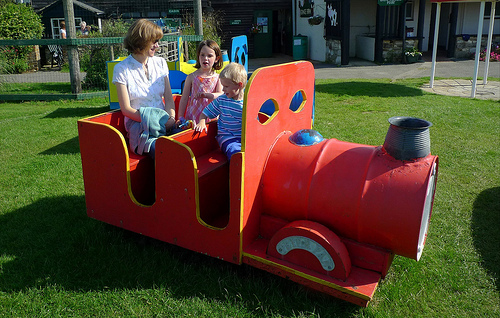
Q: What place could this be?
A: It is a park.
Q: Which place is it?
A: It is a park.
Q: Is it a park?
A: Yes, it is a park.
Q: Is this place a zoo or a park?
A: It is a park.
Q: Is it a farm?
A: No, it is a park.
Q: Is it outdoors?
A: Yes, it is outdoors.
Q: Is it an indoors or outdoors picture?
A: It is outdoors.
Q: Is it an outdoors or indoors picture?
A: It is outdoors.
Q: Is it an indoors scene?
A: No, it is outdoors.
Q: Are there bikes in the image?
A: No, there are no bikes.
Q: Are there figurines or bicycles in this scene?
A: No, there are no bicycles or figurines.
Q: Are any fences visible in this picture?
A: Yes, there is a fence.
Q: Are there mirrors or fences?
A: Yes, there is a fence.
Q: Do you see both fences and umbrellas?
A: No, there is a fence but no umbrellas.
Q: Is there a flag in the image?
A: No, there are no flags.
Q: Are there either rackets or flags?
A: No, there are no flags or rackets.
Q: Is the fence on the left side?
A: Yes, the fence is on the left of the image.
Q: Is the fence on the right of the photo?
A: No, the fence is on the left of the image.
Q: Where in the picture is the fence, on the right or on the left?
A: The fence is on the left of the image.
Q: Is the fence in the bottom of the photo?
A: No, the fence is in the top of the image.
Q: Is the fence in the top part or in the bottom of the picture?
A: The fence is in the top of the image.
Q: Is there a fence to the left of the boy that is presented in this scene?
A: Yes, there is a fence to the left of the boy.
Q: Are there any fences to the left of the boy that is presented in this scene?
A: Yes, there is a fence to the left of the boy.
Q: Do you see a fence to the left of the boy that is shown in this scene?
A: Yes, there is a fence to the left of the boy.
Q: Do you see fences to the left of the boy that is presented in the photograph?
A: Yes, there is a fence to the left of the boy.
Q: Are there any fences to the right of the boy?
A: No, the fence is to the left of the boy.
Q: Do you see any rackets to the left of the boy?
A: No, there is a fence to the left of the boy.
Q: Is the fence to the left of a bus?
A: No, the fence is to the left of a boy.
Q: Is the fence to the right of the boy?
A: No, the fence is to the left of the boy.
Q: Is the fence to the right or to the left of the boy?
A: The fence is to the left of the boy.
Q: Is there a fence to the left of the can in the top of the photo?
A: Yes, there is a fence to the left of the can.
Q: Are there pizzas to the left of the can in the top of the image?
A: No, there is a fence to the left of the can.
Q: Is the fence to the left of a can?
A: Yes, the fence is to the left of a can.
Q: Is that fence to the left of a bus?
A: No, the fence is to the left of a can.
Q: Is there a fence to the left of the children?
A: Yes, there is a fence to the left of the children.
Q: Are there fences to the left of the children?
A: Yes, there is a fence to the left of the children.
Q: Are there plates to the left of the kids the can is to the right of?
A: No, there is a fence to the left of the kids.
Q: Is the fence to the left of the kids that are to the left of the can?
A: Yes, the fence is to the left of the kids.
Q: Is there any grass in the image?
A: Yes, there is grass.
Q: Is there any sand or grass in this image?
A: Yes, there is grass.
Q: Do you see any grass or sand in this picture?
A: Yes, there is grass.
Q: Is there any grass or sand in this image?
A: Yes, there is grass.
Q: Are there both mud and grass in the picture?
A: No, there is grass but no mud.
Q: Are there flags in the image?
A: No, there are no flags.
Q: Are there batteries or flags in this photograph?
A: No, there are no flags or batteries.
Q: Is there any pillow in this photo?
A: No, there are no pillows.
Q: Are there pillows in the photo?
A: No, there are no pillows.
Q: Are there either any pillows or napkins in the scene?
A: No, there are no pillows or napkins.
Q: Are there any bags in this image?
A: No, there are no bags.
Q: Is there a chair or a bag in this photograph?
A: No, there are no bags or chairs.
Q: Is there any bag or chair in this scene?
A: No, there are no bags or chairs.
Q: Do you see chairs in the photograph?
A: No, there are no chairs.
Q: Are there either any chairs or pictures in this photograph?
A: No, there are no chairs or pictures.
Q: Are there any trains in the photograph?
A: Yes, there is a train.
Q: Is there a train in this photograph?
A: Yes, there is a train.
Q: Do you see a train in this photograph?
A: Yes, there is a train.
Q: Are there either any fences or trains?
A: Yes, there is a train.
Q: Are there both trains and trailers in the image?
A: No, there is a train but no trailers.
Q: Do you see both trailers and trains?
A: No, there is a train but no trailers.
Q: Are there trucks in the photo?
A: No, there are no trucks.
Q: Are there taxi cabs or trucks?
A: No, there are no trucks or taxi cabs.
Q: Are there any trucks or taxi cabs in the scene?
A: No, there are no trucks or taxi cabs.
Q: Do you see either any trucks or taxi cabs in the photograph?
A: No, there are no trucks or taxi cabs.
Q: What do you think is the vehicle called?
A: The vehicle is a train.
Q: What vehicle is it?
A: The vehicle is a train.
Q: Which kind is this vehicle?
A: This is a train.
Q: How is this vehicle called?
A: This is a train.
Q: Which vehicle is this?
A: This is a train.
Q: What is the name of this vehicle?
A: This is a train.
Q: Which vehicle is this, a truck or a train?
A: This is a train.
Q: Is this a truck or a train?
A: This is a train.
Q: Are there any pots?
A: No, there are no pots.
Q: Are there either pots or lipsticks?
A: No, there are no pots or lipsticks.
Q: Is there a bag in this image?
A: No, there are no bags.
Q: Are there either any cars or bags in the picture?
A: No, there are no bags or cars.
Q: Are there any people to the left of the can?
A: Yes, there are people to the left of the can.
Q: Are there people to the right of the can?
A: No, the people are to the left of the can.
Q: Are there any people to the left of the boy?
A: Yes, there are people to the left of the boy.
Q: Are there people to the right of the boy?
A: No, the people are to the left of the boy.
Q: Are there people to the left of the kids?
A: Yes, there are people to the left of the kids.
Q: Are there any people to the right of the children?
A: No, the people are to the left of the children.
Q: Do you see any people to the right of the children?
A: No, the people are to the left of the children.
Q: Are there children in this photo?
A: Yes, there are children.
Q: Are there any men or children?
A: Yes, there are children.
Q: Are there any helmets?
A: No, there are no helmets.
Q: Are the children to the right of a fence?
A: Yes, the children are to the right of a fence.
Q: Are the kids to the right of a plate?
A: No, the kids are to the right of a fence.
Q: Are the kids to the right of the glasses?
A: Yes, the kids are to the right of the glasses.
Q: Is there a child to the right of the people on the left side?
A: Yes, there are children to the right of the people.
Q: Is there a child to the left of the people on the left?
A: No, the children are to the right of the people.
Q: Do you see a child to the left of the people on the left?
A: No, the children are to the right of the people.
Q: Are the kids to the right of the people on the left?
A: Yes, the kids are to the right of the people.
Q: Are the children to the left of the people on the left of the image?
A: No, the children are to the right of the people.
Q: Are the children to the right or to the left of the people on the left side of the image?
A: The children are to the right of the people.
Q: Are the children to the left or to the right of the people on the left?
A: The children are to the right of the people.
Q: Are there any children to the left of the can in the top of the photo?
A: Yes, there are children to the left of the can.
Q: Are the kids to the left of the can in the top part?
A: Yes, the kids are to the left of the can.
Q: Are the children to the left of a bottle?
A: No, the children are to the left of the can.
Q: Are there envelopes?
A: No, there are no envelopes.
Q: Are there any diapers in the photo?
A: No, there are no diapers.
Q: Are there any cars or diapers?
A: No, there are no diapers or cars.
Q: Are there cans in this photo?
A: Yes, there is a can.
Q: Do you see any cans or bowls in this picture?
A: Yes, there is a can.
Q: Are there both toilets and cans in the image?
A: No, there is a can but no toilets.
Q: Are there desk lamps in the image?
A: No, there are no desk lamps.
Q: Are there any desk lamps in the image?
A: No, there are no desk lamps.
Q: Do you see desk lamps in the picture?
A: No, there are no desk lamps.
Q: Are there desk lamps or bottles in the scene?
A: No, there are no desk lamps or bottles.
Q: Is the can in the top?
A: Yes, the can is in the top of the image.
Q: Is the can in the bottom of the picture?
A: No, the can is in the top of the image.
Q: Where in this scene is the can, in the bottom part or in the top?
A: The can is in the top of the image.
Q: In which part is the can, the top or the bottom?
A: The can is in the top of the image.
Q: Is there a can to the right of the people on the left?
A: Yes, there is a can to the right of the people.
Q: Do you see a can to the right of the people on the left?
A: Yes, there is a can to the right of the people.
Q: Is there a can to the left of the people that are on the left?
A: No, the can is to the right of the people.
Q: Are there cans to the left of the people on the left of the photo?
A: No, the can is to the right of the people.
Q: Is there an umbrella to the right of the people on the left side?
A: No, there is a can to the right of the people.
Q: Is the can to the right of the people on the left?
A: Yes, the can is to the right of the people.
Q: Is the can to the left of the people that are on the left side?
A: No, the can is to the right of the people.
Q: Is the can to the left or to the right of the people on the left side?
A: The can is to the right of the people.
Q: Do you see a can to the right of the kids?
A: Yes, there is a can to the right of the kids.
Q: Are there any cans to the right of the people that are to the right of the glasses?
A: Yes, there is a can to the right of the kids.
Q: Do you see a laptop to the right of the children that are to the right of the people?
A: No, there is a can to the right of the children.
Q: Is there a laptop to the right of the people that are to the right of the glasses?
A: No, there is a can to the right of the children.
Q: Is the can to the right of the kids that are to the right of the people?
A: Yes, the can is to the right of the children.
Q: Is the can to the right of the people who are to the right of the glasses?
A: Yes, the can is to the right of the children.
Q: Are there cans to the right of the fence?
A: Yes, there is a can to the right of the fence.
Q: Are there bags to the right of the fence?
A: No, there is a can to the right of the fence.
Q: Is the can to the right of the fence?
A: Yes, the can is to the right of the fence.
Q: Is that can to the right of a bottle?
A: No, the can is to the right of the fence.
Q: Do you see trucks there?
A: No, there are no trucks.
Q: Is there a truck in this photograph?
A: No, there are no trucks.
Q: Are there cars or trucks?
A: No, there are no trucks or cars.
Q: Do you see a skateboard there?
A: No, there are no skateboards.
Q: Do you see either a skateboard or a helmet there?
A: No, there are no skateboards or helmets.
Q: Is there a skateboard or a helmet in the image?
A: No, there are no skateboards or helmets.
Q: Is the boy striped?
A: Yes, the boy is striped.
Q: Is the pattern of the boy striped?
A: Yes, the boy is striped.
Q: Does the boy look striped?
A: Yes, the boy is striped.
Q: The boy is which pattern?
A: The boy is striped.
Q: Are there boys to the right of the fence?
A: Yes, there is a boy to the right of the fence.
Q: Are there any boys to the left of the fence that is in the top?
A: No, the boy is to the right of the fence.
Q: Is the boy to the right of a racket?
A: No, the boy is to the right of the fence.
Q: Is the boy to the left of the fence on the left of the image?
A: No, the boy is to the right of the fence.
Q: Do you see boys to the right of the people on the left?
A: Yes, there is a boy to the right of the people.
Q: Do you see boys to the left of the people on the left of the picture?
A: No, the boy is to the right of the people.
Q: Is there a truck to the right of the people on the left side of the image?
A: No, there is a boy to the right of the people.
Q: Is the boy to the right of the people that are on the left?
A: Yes, the boy is to the right of the people.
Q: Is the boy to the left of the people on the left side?
A: No, the boy is to the right of the people.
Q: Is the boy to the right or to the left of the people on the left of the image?
A: The boy is to the right of the people.